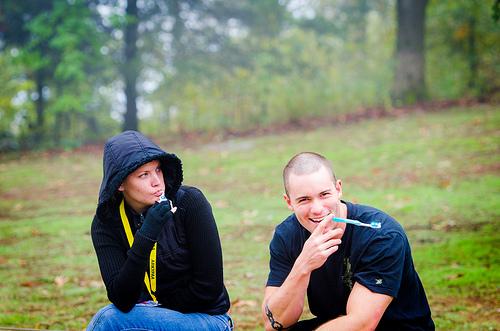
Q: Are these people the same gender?
A: No, they are both male and female.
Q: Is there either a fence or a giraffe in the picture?
A: No, there are no fences or giraffes.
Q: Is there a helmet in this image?
A: No, there are no helmets.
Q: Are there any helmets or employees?
A: No, there are no helmets or employees.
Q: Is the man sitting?
A: Yes, the man is sitting.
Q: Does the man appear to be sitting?
A: Yes, the man is sitting.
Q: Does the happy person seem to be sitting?
A: Yes, the man is sitting.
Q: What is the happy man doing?
A: The man is sitting.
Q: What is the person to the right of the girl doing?
A: The man is sitting.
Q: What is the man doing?
A: The man is sitting.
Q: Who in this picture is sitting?
A: The man is sitting.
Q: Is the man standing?
A: No, the man is sitting.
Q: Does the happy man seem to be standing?
A: No, the man is sitting.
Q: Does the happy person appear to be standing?
A: No, the man is sitting.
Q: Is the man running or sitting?
A: The man is sitting.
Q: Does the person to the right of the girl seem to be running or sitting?
A: The man is sitting.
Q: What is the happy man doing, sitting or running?
A: The man is sitting.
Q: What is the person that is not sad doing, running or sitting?
A: The man is sitting.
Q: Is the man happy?
A: Yes, the man is happy.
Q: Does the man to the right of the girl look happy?
A: Yes, the man is happy.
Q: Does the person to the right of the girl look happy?
A: Yes, the man is happy.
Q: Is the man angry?
A: No, the man is happy.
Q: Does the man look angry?
A: No, the man is happy.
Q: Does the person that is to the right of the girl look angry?
A: No, the man is happy.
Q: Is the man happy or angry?
A: The man is happy.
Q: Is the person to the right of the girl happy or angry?
A: The man is happy.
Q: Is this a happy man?
A: Yes, this is a happy man.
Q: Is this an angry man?
A: No, this is a happy man.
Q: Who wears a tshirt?
A: The man wears a tshirt.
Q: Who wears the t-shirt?
A: The man wears a tshirt.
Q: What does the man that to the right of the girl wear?
A: The man wears a tshirt.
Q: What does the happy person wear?
A: The man wears a tshirt.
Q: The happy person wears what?
A: The man wears a tshirt.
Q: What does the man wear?
A: The man wears a tshirt.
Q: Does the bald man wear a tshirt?
A: Yes, the man wears a tshirt.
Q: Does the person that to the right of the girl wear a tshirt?
A: Yes, the man wears a tshirt.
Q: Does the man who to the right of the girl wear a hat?
A: No, the man wears a tshirt.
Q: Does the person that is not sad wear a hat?
A: No, the man wears a tshirt.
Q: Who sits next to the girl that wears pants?
A: The man sits next to the girl.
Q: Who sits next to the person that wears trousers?
A: The man sits next to the girl.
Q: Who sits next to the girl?
A: The man sits next to the girl.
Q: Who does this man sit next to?
A: The man sits next to the girl.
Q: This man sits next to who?
A: The man sits next to the girl.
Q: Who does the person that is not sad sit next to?
A: The man sits next to the girl.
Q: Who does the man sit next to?
A: The man sits next to the girl.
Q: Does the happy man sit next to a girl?
A: Yes, the man sits next to a girl.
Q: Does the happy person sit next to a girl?
A: Yes, the man sits next to a girl.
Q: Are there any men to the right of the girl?
A: Yes, there is a man to the right of the girl.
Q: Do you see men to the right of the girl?
A: Yes, there is a man to the right of the girl.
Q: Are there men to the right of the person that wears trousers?
A: Yes, there is a man to the right of the girl.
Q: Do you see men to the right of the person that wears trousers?
A: Yes, there is a man to the right of the girl.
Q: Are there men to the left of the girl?
A: No, the man is to the right of the girl.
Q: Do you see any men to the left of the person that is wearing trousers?
A: No, the man is to the right of the girl.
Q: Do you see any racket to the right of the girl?
A: No, there is a man to the right of the girl.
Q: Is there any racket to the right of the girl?
A: No, there is a man to the right of the girl.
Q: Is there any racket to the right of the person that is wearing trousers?
A: No, there is a man to the right of the girl.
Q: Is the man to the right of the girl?
A: Yes, the man is to the right of the girl.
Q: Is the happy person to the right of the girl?
A: Yes, the man is to the right of the girl.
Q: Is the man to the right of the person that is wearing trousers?
A: Yes, the man is to the right of the girl.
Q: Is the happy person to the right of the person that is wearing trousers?
A: Yes, the man is to the right of the girl.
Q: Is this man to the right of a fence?
A: No, the man is to the right of the girl.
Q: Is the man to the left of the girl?
A: No, the man is to the right of the girl.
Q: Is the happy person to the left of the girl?
A: No, the man is to the right of the girl.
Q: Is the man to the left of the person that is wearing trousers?
A: No, the man is to the right of the girl.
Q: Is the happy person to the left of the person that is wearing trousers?
A: No, the man is to the right of the girl.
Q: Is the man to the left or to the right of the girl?
A: The man is to the right of the girl.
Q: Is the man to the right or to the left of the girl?
A: The man is to the right of the girl.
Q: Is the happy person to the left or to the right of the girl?
A: The man is to the right of the girl.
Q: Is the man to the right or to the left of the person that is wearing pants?
A: The man is to the right of the girl.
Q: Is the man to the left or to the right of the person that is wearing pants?
A: The man is to the right of the girl.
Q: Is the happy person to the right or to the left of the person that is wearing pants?
A: The man is to the right of the girl.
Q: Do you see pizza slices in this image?
A: No, there are no pizza slices.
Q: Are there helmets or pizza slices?
A: No, there are no pizza slices or helmets.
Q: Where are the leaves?
A: The leaves are on the ground.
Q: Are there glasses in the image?
A: No, there are no glasses.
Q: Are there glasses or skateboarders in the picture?
A: No, there are no glasses or skateboarders.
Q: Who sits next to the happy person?
A: The girl sits next to the man.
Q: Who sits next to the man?
A: The girl sits next to the man.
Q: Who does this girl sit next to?
A: The girl sits next to the man.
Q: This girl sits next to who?
A: The girl sits next to the man.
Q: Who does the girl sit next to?
A: The girl sits next to the man.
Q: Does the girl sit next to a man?
A: Yes, the girl sits next to a man.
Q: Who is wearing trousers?
A: The girl is wearing trousers.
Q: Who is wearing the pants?
A: The girl is wearing trousers.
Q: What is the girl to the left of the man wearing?
A: The girl is wearing trousers.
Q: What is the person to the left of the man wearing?
A: The girl is wearing trousers.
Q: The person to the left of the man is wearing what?
A: The girl is wearing trousers.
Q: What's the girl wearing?
A: The girl is wearing trousers.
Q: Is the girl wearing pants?
A: Yes, the girl is wearing pants.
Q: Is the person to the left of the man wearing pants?
A: Yes, the girl is wearing pants.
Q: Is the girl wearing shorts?
A: No, the girl is wearing pants.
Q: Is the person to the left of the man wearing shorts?
A: No, the girl is wearing pants.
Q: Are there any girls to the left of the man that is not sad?
A: Yes, there is a girl to the left of the man.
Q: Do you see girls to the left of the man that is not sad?
A: Yes, there is a girl to the left of the man.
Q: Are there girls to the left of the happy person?
A: Yes, there is a girl to the left of the man.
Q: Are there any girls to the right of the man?
A: No, the girl is to the left of the man.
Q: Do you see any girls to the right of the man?
A: No, the girl is to the left of the man.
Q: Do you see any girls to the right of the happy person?
A: No, the girl is to the left of the man.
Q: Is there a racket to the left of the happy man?
A: No, there is a girl to the left of the man.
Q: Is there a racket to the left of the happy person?
A: No, there is a girl to the left of the man.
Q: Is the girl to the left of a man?
A: Yes, the girl is to the left of a man.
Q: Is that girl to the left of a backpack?
A: No, the girl is to the left of a man.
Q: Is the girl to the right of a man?
A: No, the girl is to the left of a man.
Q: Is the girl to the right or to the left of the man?
A: The girl is to the left of the man.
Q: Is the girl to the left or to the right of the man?
A: The girl is to the left of the man.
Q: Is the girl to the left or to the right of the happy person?
A: The girl is to the left of the man.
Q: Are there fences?
A: No, there are no fences.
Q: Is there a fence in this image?
A: No, there are no fences.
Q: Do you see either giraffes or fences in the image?
A: No, there are no fences or giraffes.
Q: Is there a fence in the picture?
A: No, there are no fences.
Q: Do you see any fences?
A: No, there are no fences.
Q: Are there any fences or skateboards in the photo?
A: No, there are no fences or skateboards.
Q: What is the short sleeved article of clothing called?
A: The clothing item is a t-shirt.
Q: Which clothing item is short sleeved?
A: The clothing item is a t-shirt.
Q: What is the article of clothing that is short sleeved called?
A: The clothing item is a t-shirt.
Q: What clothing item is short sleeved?
A: The clothing item is a t-shirt.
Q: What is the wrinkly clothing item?
A: The clothing item is a t-shirt.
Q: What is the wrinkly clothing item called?
A: The clothing item is a t-shirt.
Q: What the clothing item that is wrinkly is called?
A: The clothing item is a t-shirt.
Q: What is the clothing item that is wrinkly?
A: The clothing item is a t-shirt.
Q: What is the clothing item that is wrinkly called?
A: The clothing item is a t-shirt.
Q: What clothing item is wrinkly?
A: The clothing item is a t-shirt.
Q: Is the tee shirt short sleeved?
A: Yes, the tee shirt is short sleeved.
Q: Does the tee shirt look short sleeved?
A: Yes, the tee shirt is short sleeved.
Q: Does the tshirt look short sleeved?
A: Yes, the tshirt is short sleeved.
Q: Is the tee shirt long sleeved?
A: No, the tee shirt is short sleeved.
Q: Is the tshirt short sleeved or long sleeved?
A: The tshirt is short sleeved.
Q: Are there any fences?
A: No, there are no fences.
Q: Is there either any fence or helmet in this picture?
A: No, there are no fences or helmets.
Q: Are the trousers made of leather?
A: No, the trousers are made of jeans.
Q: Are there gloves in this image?
A: Yes, there are gloves.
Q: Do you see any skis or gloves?
A: Yes, there are gloves.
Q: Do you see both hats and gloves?
A: No, there are gloves but no hats.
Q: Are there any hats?
A: No, there are no hats.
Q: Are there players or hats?
A: No, there are no hats or players.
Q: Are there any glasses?
A: No, there are no glasses.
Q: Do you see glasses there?
A: No, there are no glasses.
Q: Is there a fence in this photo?
A: No, there are no fences.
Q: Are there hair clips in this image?
A: No, there are no hair clips.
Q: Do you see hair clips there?
A: No, there are no hair clips.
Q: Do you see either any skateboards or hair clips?
A: No, there are no hair clips or skateboards.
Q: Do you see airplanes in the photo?
A: No, there are no airplanes.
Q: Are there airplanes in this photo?
A: No, there are no airplanes.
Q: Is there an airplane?
A: No, there are no airplanes.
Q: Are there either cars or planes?
A: No, there are no planes or cars.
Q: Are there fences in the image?
A: No, there are no fences.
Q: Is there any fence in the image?
A: No, there are no fences.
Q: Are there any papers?
A: No, there are no papers.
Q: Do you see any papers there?
A: No, there are no papers.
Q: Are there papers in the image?
A: No, there are no papers.